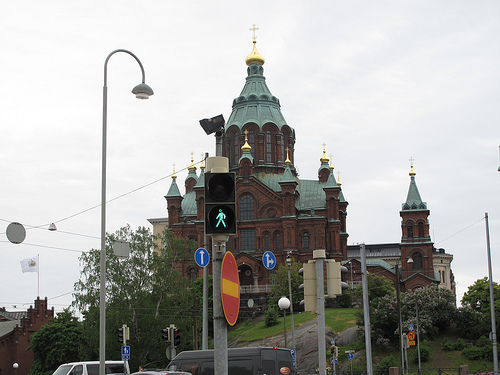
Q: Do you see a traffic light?
A: Yes, there is a traffic light.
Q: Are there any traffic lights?
A: Yes, there is a traffic light.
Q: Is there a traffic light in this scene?
A: Yes, there is a traffic light.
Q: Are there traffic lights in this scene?
A: Yes, there is a traffic light.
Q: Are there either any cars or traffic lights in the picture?
A: Yes, there is a traffic light.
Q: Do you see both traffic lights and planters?
A: No, there is a traffic light but no planters.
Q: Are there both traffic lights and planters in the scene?
A: No, there is a traffic light but no planters.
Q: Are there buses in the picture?
A: No, there are no buses.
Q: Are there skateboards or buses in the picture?
A: No, there are no buses or skateboards.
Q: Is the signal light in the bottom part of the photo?
A: Yes, the signal light is in the bottom of the image.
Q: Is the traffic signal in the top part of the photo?
A: No, the traffic signal is in the bottom of the image.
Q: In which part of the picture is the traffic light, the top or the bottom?
A: The traffic light is in the bottom of the image.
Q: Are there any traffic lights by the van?
A: Yes, there is a traffic light by the van.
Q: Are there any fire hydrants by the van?
A: No, there is a traffic light by the van.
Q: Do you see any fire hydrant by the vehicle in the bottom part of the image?
A: No, there is a traffic light by the van.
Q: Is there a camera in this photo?
A: Yes, there is a camera.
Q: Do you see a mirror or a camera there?
A: Yes, there is a camera.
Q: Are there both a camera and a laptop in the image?
A: No, there is a camera but no laptops.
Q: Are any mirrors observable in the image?
A: No, there are no mirrors.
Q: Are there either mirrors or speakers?
A: No, there are no mirrors or speakers.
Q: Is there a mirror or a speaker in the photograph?
A: No, there are no mirrors or speakers.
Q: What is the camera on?
A: The camera is on the pole.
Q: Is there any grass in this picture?
A: Yes, there is grass.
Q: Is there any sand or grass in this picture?
A: Yes, there is grass.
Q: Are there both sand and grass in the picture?
A: No, there is grass but no sand.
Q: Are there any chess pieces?
A: No, there are no chess pieces.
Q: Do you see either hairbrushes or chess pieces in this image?
A: No, there are no chess pieces or hairbrushes.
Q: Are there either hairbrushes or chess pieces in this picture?
A: No, there are no chess pieces or hairbrushes.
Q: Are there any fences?
A: No, there are no fences.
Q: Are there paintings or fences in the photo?
A: No, there are no fences or paintings.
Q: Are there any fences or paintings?
A: No, there are no fences or paintings.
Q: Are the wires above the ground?
A: Yes, the wires are above the ground.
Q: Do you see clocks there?
A: No, there are no clocks.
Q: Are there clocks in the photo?
A: No, there are no clocks.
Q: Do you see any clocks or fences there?
A: No, there are no clocks or fences.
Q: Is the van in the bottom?
A: Yes, the van is in the bottom of the image.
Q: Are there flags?
A: Yes, there is a flag.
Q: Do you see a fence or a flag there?
A: Yes, there is a flag.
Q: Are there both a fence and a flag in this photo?
A: No, there is a flag but no fences.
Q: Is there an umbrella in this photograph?
A: No, there are no umbrellas.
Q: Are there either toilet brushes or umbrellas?
A: No, there are no umbrellas or toilet brushes.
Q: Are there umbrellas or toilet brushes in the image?
A: No, there are no umbrellas or toilet brushes.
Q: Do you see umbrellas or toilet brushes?
A: No, there are no umbrellas or toilet brushes.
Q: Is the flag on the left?
A: Yes, the flag is on the left of the image.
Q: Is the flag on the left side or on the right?
A: The flag is on the left of the image.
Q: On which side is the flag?
A: The flag is on the left of the image.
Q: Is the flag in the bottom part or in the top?
A: The flag is in the bottom of the image.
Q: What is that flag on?
A: The flag is on the building.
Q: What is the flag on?
A: The flag is on the building.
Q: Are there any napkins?
A: No, there are no napkins.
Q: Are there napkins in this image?
A: No, there are no napkins.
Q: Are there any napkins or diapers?
A: No, there are no napkins or diapers.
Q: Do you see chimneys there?
A: No, there are no chimneys.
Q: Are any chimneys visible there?
A: No, there are no chimneys.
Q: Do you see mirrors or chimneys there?
A: No, there are no chimneys or mirrors.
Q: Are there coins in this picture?
A: No, there are no coins.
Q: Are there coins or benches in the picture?
A: No, there are no coins or benches.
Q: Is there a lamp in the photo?
A: Yes, there is a lamp.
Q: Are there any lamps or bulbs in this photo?
A: Yes, there is a lamp.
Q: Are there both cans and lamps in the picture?
A: No, there is a lamp but no cans.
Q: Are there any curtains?
A: No, there are no curtains.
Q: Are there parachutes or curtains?
A: No, there are no curtains or parachutes.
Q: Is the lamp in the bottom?
A: Yes, the lamp is in the bottom of the image.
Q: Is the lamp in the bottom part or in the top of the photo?
A: The lamp is in the bottom of the image.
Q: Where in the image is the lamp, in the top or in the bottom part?
A: The lamp is in the bottom of the image.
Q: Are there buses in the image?
A: No, there are no buses.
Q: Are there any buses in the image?
A: No, there are no buses.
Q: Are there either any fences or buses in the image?
A: No, there are no buses or fences.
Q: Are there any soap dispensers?
A: No, there are no soap dispensers.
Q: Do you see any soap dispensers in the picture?
A: No, there are no soap dispensers.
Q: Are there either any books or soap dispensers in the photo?
A: No, there are no soap dispensers or books.